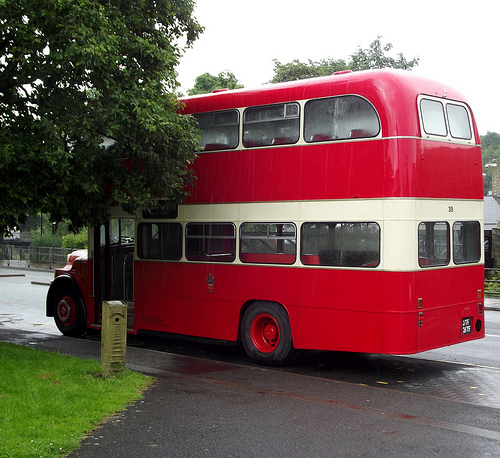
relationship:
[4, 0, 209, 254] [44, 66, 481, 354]
tree obscuring bus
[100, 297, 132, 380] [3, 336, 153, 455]
pole in grass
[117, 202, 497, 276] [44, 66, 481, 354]
band on bus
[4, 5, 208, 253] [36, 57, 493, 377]
tree by bus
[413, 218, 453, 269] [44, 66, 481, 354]
window on a bus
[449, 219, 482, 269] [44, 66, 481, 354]
window on a bus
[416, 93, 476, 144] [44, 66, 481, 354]
back window on a bus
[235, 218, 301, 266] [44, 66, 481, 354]
window on a bus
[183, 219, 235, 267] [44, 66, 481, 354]
window on a bus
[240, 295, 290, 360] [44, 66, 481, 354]
tire on a bus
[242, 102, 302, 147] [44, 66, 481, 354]
window on a bus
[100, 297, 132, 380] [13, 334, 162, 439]
pole in yard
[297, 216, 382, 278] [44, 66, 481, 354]
window in side of bus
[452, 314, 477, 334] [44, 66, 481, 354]
license plate back of bus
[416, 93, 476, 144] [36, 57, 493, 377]
back window of bus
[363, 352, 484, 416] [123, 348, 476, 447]
brick inlaid in street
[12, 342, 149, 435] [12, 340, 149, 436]
patch of grass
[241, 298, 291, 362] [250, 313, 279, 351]
tire with a hubcap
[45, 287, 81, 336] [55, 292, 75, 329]
tire with a hubcap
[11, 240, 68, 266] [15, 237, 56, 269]
section of fencing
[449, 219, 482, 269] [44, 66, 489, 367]
window on bus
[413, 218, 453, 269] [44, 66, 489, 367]
window on bus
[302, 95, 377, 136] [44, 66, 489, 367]
window on bus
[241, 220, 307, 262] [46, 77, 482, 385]
window on vehicle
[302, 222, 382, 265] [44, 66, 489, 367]
window on bus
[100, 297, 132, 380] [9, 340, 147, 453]
pole in grass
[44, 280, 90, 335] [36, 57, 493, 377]
wheel of bus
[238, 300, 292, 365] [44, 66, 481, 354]
back wheel on bus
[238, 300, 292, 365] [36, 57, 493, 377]
back wheel on bus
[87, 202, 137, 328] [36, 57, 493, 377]
entrance on bus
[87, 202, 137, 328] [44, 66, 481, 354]
entrance on bus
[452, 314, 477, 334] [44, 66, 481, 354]
license plate on bus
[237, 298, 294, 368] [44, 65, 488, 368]
tire on tour bus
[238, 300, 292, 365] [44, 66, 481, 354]
back wheel mounted on bus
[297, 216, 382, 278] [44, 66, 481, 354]
window built into bus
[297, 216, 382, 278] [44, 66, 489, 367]
window on bus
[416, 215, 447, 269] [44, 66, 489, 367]
window on bus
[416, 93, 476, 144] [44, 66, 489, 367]
back window on bus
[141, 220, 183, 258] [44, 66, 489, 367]
window on bus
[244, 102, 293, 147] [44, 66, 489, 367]
window on bus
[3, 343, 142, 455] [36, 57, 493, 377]
area near bus